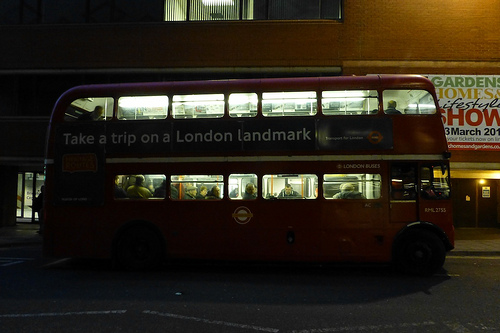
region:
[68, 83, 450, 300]
the bus is a double decker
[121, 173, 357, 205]
people are in a bus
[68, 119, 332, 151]
the letters say take a trip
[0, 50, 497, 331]
the scene is in britain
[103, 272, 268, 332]
the road is grey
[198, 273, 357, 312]
shadow is on th eroad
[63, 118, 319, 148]
the letters are white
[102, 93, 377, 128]
the top of bus has few people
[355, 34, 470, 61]
wall is made of bricks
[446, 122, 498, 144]
the month is march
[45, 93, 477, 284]
double decker red bus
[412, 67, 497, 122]
white sign on store front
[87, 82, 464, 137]
illuminated light inside bus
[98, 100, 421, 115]
passenger windows on bus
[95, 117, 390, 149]
writing on the side of bus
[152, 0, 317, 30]
window shades in building above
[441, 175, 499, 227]
store front with light on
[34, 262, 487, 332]
paved road under bus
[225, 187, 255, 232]
small logo on side of bus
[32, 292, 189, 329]
white lines painted on street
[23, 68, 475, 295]
A double decker bus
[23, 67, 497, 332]
A red two story bus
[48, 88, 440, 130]
Windows on a bus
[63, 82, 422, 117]
Lights on inside a bus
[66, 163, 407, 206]
People inside a bus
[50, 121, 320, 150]
Sign that says Take a Trip on a London Landmark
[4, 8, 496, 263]
A building behind the bus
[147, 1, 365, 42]
A window on a building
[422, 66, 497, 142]
A sign on a building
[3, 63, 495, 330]
A bus in front of a building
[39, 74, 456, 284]
A red tour bus.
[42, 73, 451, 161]
Second level of a bus.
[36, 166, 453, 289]
First level of a bus.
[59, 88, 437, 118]
Windows on a bus.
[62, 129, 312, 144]
A sign on a bus.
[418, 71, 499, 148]
A sign on a building.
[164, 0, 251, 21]
A window on a building.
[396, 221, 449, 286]
A front wheel of a bus.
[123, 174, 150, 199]
A passenger on a bus.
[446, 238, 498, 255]
A sidewalk.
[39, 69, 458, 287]
A red double decker bus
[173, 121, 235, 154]
The word "London" on side of the bus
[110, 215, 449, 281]
Two round tires of a bus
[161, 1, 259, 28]
Window on side of a building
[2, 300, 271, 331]
White lines on the pavement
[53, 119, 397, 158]
A sign on side of a bus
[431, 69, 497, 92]
The word "GARDEN" on a sign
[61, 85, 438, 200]
Lights on inside the bus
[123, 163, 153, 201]
Person in yellow shirt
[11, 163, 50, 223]
The door of a building